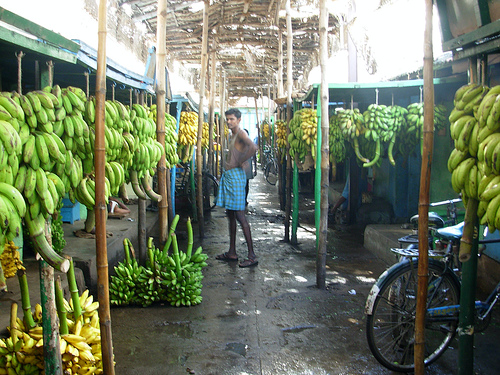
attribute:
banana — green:
[459, 153, 474, 190]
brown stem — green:
[29, 241, 88, 283]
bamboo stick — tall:
[80, 87, 127, 373]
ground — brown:
[107, 170, 417, 370]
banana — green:
[25, 139, 59, 169]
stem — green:
[27, 220, 69, 272]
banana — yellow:
[64, 333, 84, 344]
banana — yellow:
[70, 341, 90, 351]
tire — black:
[341, 242, 457, 362]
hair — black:
[216, 110, 271, 145]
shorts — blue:
[213, 167, 248, 212]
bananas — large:
[11, 93, 101, 168]